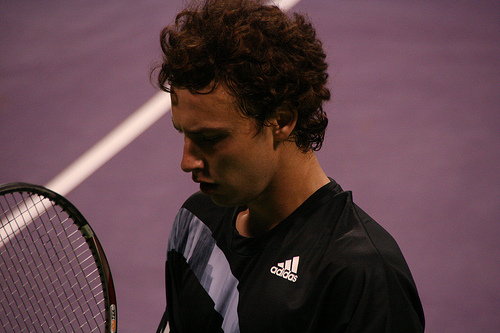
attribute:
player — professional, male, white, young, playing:
[157, 0, 424, 332]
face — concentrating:
[171, 80, 269, 206]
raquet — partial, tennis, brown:
[3, 180, 116, 332]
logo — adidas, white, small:
[272, 256, 302, 281]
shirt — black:
[167, 180, 426, 331]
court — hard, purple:
[2, 0, 499, 332]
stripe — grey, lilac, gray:
[168, 206, 240, 332]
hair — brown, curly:
[154, 2, 328, 153]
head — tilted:
[154, 3, 329, 210]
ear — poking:
[275, 98, 299, 139]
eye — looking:
[200, 135, 214, 144]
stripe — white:
[0, 0, 302, 247]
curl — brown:
[157, 67, 182, 102]